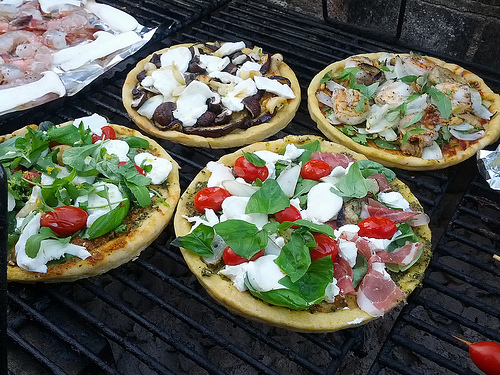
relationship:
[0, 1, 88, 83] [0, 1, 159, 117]
shrimp on tin foil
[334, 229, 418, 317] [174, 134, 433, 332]
meat on pizza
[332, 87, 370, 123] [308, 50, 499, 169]
shrimp on pizza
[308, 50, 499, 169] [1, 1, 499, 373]
pizza on grill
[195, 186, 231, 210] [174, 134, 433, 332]
tomato on pizza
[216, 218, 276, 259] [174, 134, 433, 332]
basil on pizza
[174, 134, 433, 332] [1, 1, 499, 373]
pizza on grill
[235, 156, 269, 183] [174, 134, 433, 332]
tomato on pizza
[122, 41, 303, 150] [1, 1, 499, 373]
pizza on grill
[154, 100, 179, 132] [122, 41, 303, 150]
mushroom on pizza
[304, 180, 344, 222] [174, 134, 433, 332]
mozzarella cheese on pizza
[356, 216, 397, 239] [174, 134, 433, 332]
tomato on pizza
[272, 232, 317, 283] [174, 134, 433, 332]
basil on pizza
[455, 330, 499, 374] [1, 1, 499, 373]
vegetable on grill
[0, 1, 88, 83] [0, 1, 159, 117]
shrimp in tin foil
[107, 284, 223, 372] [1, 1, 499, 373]
coal under grill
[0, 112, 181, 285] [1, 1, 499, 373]
pizza on grill